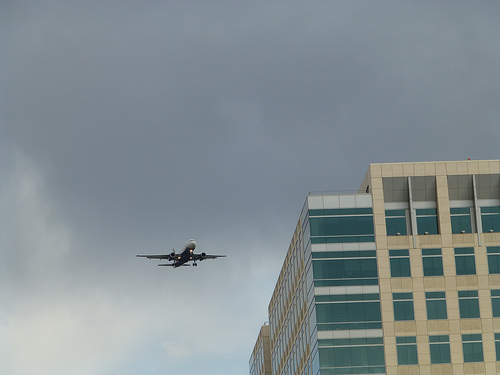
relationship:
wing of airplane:
[193, 249, 228, 264] [135, 238, 229, 270]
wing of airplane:
[136, 249, 178, 263] [135, 238, 229, 270]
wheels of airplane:
[191, 260, 200, 267] [135, 238, 229, 270]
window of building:
[324, 260, 345, 279] [243, 158, 500, 374]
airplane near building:
[135, 238, 229, 270] [243, 158, 500, 374]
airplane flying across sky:
[135, 238, 229, 270] [1, 1, 499, 373]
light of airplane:
[176, 255, 182, 262] [135, 238, 229, 270]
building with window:
[243, 158, 500, 374] [324, 260, 345, 279]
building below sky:
[243, 158, 500, 374] [1, 1, 499, 373]